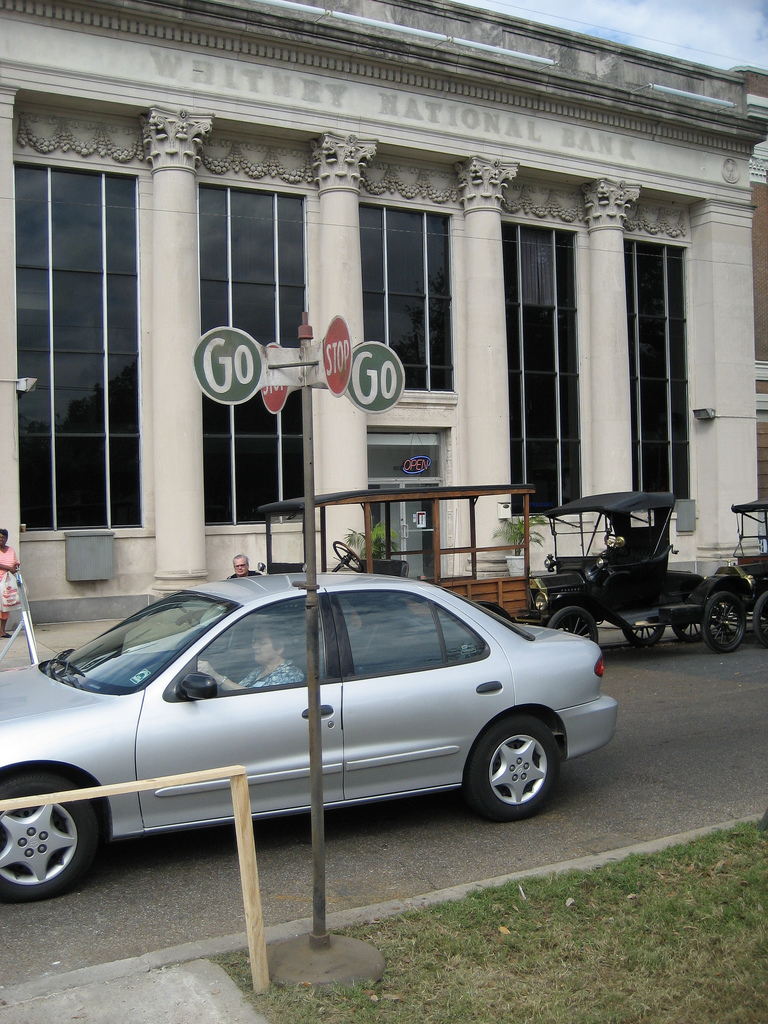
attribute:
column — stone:
[448, 168, 541, 572]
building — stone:
[7, 7, 766, 639]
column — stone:
[578, 183, 656, 547]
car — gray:
[9, 569, 641, 901]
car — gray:
[7, 564, 626, 924]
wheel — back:
[475, 698, 569, 818]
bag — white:
[1, 516, 44, 704]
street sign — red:
[325, 333, 376, 380]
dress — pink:
[1, 543, 14, 575]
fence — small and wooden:
[218, 849, 273, 948]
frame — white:
[497, 320, 517, 486]